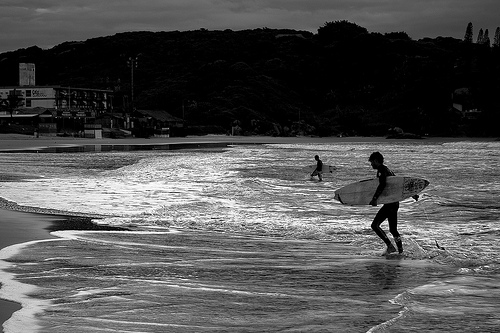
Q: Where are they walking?
A: To shore.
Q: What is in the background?
A: Trees.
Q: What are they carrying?
A: A surfboard.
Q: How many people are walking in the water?
A: Two.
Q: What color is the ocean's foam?
A: White.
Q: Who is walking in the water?
A: Two men.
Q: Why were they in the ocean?
A: Surfing.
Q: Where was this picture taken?
A: A beach.